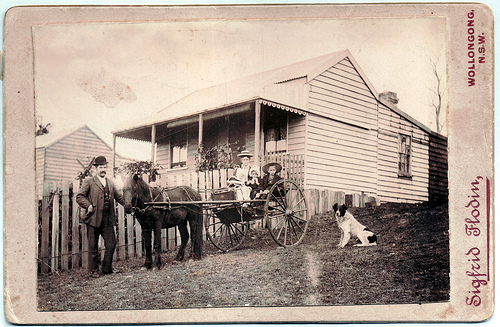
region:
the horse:
[87, 128, 225, 290]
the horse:
[104, 176, 262, 321]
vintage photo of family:
[40, 38, 445, 285]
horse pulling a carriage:
[114, 161, 210, 273]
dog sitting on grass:
[325, 194, 382, 257]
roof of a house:
[107, 37, 445, 132]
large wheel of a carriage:
[257, 174, 316, 251]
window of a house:
[167, 130, 193, 169]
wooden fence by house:
[39, 182, 82, 280]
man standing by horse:
[72, 147, 134, 280]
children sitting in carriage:
[247, 160, 287, 205]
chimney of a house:
[376, 86, 404, 116]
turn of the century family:
[66, 34, 386, 312]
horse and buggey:
[120, 155, 317, 257]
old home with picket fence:
[106, 47, 443, 248]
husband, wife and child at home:
[76, 140, 315, 299]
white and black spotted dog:
[329, 191, 392, 263]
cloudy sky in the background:
[63, 55, 158, 105]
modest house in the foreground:
[112, 52, 439, 262]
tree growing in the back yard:
[412, 55, 447, 151]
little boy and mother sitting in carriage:
[219, 140, 295, 240]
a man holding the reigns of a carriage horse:
[69, 134, 221, 284]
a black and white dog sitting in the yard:
[331, 202, 380, 247]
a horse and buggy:
[123, 150, 309, 269]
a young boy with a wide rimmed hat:
[258, 161, 283, 197]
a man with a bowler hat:
[76, 154, 123, 278]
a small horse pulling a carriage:
[118, 172, 205, 270]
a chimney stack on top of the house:
[378, 88, 398, 105]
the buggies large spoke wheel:
[264, 178, 308, 248]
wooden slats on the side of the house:
[303, 48, 448, 205]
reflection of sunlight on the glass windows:
[169, 126, 189, 167]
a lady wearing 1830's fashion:
[227, 148, 257, 203]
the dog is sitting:
[293, 155, 400, 312]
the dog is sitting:
[300, 178, 355, 293]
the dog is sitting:
[312, 218, 392, 285]